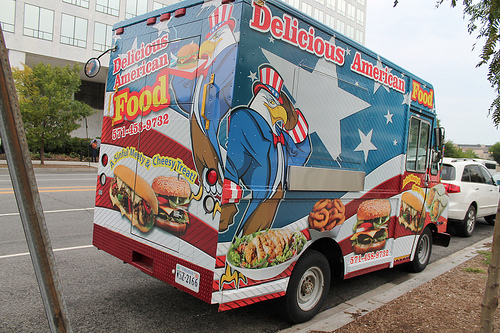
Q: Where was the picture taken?
A: It was taken at the roadway.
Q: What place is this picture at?
A: It is at the roadway.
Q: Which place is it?
A: It is a roadway.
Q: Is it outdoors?
A: Yes, it is outdoors.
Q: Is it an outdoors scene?
A: Yes, it is outdoors.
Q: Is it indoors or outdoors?
A: It is outdoors.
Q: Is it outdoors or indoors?
A: It is outdoors.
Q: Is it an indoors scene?
A: No, it is outdoors.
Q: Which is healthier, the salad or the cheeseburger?
A: The salad is healthier than the cheeseburger.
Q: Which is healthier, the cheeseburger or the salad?
A: The salad is healthier than the cheeseburger.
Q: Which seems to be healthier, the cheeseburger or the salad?
A: The salad is healthier than the cheeseburger.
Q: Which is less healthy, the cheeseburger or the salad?
A: The cheeseburger is less healthy than the salad.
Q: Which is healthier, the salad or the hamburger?
A: The salad is healthier than the hamburger.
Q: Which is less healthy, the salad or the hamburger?
A: The hamburger is less healthy than the salad.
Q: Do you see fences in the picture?
A: No, there are no fences.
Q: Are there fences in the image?
A: No, there are no fences.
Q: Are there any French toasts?
A: No, there are no French toasts.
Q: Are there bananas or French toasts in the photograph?
A: No, there are no French toasts or bananas.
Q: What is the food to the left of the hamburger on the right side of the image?
A: The food is onion rings.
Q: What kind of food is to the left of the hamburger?
A: The food is onion rings.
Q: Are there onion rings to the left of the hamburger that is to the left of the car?
A: Yes, there are onion rings to the left of the hamburger.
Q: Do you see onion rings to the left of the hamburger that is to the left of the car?
A: Yes, there are onion rings to the left of the hamburger.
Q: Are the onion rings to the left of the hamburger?
A: Yes, the onion rings are to the left of the hamburger.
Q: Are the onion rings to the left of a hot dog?
A: No, the onion rings are to the left of the hamburger.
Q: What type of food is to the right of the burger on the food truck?
A: The food is onion rings.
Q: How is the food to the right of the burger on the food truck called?
A: The food is onion rings.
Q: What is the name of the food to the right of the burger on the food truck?
A: The food is onion rings.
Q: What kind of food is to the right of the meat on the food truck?
A: The food is onion rings.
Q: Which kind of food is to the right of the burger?
A: The food is onion rings.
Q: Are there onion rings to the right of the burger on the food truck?
A: Yes, there are onion rings to the right of the burger.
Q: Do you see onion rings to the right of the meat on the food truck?
A: Yes, there are onion rings to the right of the burger.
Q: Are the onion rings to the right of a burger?
A: Yes, the onion rings are to the right of a burger.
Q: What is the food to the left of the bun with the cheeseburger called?
A: The food is onion rings.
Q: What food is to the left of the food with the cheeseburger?
A: The food is onion rings.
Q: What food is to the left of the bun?
A: The food is onion rings.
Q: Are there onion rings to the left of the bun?
A: Yes, there are onion rings to the left of the bun.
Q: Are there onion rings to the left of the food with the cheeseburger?
A: Yes, there are onion rings to the left of the bun.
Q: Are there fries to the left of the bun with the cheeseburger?
A: No, there are onion rings to the left of the bun.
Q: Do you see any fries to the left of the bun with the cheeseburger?
A: No, there are onion rings to the left of the bun.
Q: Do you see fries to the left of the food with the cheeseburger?
A: No, there are onion rings to the left of the bun.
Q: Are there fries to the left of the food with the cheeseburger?
A: No, there are onion rings to the left of the bun.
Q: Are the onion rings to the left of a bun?
A: Yes, the onion rings are to the left of a bun.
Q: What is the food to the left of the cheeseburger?
A: The food is onion rings.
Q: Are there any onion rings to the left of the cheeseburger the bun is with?
A: Yes, there are onion rings to the left of the cheeseburger.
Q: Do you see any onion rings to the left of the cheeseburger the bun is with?
A: Yes, there are onion rings to the left of the cheeseburger.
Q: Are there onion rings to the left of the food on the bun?
A: Yes, there are onion rings to the left of the cheeseburger.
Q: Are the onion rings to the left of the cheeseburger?
A: Yes, the onion rings are to the left of the cheeseburger.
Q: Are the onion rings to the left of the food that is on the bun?
A: Yes, the onion rings are to the left of the cheeseburger.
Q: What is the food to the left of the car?
A: The food is onion rings.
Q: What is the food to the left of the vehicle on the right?
A: The food is onion rings.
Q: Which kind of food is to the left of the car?
A: The food is onion rings.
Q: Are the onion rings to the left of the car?
A: Yes, the onion rings are to the left of the car.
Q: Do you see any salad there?
A: Yes, there is salad.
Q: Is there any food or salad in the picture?
A: Yes, there is salad.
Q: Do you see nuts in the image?
A: No, there are no nuts.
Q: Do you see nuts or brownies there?
A: No, there are no nuts or brownies.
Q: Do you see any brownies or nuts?
A: No, there are no nuts or brownies.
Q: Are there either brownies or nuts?
A: No, there are no nuts or brownies.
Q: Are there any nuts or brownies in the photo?
A: No, there are no nuts or brownies.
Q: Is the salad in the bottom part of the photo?
A: Yes, the salad is in the bottom of the image.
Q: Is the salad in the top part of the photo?
A: No, the salad is in the bottom of the image.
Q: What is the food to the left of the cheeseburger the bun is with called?
A: The food is salad.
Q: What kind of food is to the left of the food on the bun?
A: The food is salad.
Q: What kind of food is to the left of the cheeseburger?
A: The food is salad.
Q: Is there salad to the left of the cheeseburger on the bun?
A: Yes, there is salad to the left of the cheeseburger.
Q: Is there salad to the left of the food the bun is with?
A: Yes, there is salad to the left of the cheeseburger.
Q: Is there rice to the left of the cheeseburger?
A: No, there is salad to the left of the cheeseburger.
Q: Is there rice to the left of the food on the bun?
A: No, there is salad to the left of the cheeseburger.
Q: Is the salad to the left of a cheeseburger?
A: Yes, the salad is to the left of a cheeseburger.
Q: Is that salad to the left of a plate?
A: No, the salad is to the left of a cheeseburger.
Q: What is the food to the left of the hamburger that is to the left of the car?
A: The food is salad.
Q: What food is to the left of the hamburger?
A: The food is salad.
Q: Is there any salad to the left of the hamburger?
A: Yes, there is salad to the left of the hamburger.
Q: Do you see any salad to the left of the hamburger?
A: Yes, there is salad to the left of the hamburger.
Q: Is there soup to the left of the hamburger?
A: No, there is salad to the left of the hamburger.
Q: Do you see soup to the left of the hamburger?
A: No, there is salad to the left of the hamburger.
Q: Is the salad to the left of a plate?
A: No, the salad is to the left of a hamburger.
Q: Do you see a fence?
A: No, there are no fences.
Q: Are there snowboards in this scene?
A: No, there are no snowboards.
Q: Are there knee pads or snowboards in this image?
A: No, there are no snowboards or knee pads.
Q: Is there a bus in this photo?
A: No, there are no buses.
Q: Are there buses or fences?
A: No, there are no buses or fences.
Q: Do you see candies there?
A: No, there are no candies.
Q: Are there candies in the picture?
A: No, there are no candies.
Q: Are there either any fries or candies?
A: No, there are no candies or fries.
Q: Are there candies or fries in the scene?
A: No, there are no candies or fries.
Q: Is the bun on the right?
A: Yes, the bun is on the right of the image.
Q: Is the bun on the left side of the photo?
A: No, the bun is on the right of the image.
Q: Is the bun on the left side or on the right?
A: The bun is on the right of the image.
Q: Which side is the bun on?
A: The bun is on the right of the image.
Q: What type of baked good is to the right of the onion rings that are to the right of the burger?
A: The food is a bun.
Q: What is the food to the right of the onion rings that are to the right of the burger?
A: The food is a bun.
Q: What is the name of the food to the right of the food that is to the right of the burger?
A: The food is a bun.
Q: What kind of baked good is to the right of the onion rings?
A: The food is a bun.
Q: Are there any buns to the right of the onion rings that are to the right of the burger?
A: Yes, there is a bun to the right of the onion rings.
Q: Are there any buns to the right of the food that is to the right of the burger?
A: Yes, there is a bun to the right of the onion rings.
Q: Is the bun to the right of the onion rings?
A: Yes, the bun is to the right of the onion rings.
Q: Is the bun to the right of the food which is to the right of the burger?
A: Yes, the bun is to the right of the onion rings.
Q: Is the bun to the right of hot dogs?
A: No, the bun is to the right of the onion rings.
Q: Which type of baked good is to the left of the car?
A: The food is a bun.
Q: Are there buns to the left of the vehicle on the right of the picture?
A: Yes, there is a bun to the left of the car.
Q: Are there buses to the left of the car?
A: No, there is a bun to the left of the car.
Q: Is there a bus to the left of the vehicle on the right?
A: No, there is a bun to the left of the car.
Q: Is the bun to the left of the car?
A: Yes, the bun is to the left of the car.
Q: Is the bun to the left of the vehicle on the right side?
A: Yes, the bun is to the left of the car.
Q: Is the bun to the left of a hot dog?
A: No, the bun is to the left of the car.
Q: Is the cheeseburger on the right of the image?
A: Yes, the cheeseburger is on the right of the image.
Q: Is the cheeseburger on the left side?
A: No, the cheeseburger is on the right of the image.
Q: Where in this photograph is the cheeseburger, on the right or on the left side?
A: The cheeseburger is on the right of the image.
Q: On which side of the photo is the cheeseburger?
A: The cheeseburger is on the right of the image.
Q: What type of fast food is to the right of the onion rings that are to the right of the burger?
A: The food is a cheeseburger.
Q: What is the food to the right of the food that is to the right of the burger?
A: The food is a cheeseburger.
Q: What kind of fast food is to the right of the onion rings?
A: The food is a cheeseburger.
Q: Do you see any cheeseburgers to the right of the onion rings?
A: Yes, there is a cheeseburger to the right of the onion rings.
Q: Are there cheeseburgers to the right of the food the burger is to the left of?
A: Yes, there is a cheeseburger to the right of the onion rings.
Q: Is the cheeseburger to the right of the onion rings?
A: Yes, the cheeseburger is to the right of the onion rings.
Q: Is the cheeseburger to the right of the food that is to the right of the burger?
A: Yes, the cheeseburger is to the right of the onion rings.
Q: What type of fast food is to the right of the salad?
A: The food is a cheeseburger.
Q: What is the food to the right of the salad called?
A: The food is a cheeseburger.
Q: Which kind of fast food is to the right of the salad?
A: The food is a cheeseburger.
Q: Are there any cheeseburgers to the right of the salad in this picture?
A: Yes, there is a cheeseburger to the right of the salad.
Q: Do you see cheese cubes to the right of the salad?
A: No, there is a cheeseburger to the right of the salad.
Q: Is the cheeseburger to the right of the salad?
A: Yes, the cheeseburger is to the right of the salad.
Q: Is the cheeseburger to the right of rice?
A: No, the cheeseburger is to the right of the salad.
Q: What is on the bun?
A: The cheeseburger is on the bun.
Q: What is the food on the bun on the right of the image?
A: The food is a cheeseburger.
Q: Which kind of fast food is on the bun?
A: The food is a cheeseburger.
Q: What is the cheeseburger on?
A: The cheeseburger is on the bun.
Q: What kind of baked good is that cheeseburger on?
A: The cheeseburger is on the bun.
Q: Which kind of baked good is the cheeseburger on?
A: The cheeseburger is on the bun.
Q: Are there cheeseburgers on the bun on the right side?
A: Yes, there is a cheeseburger on the bun.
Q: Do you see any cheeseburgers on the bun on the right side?
A: Yes, there is a cheeseburger on the bun.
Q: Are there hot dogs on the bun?
A: No, there is a cheeseburger on the bun.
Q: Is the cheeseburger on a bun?
A: Yes, the cheeseburger is on a bun.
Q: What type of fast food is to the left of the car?
A: The food is a cheeseburger.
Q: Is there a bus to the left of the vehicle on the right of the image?
A: No, there is a cheeseburger to the left of the car.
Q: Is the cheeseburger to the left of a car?
A: Yes, the cheeseburger is to the left of a car.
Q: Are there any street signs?
A: Yes, there is a street sign.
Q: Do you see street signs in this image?
A: Yes, there is a street sign.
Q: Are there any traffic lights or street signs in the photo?
A: Yes, there is a street sign.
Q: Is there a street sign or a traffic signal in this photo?
A: Yes, there is a street sign.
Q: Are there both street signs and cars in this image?
A: Yes, there are both a street sign and a car.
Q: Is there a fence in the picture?
A: No, there are no fences.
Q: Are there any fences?
A: No, there are no fences.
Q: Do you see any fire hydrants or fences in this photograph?
A: No, there are no fences or fire hydrants.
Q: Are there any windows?
A: Yes, there is a window.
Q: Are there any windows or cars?
A: Yes, there is a window.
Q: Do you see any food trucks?
A: Yes, there is a food truck.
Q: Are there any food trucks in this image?
A: Yes, there is a food truck.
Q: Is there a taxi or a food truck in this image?
A: Yes, there is a food truck.